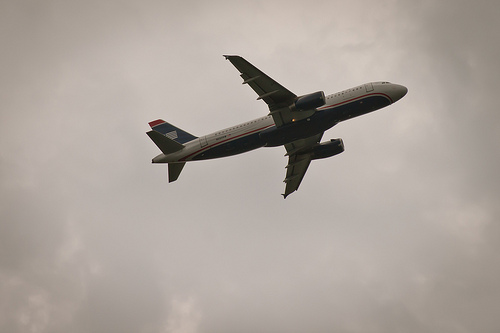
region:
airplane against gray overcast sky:
[20, 13, 478, 316]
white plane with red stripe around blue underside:
[136, 43, 409, 198]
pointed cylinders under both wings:
[219, 48, 297, 205]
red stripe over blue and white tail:
[141, 112, 199, 153]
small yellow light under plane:
[266, 98, 322, 143]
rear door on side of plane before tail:
[182, 123, 213, 166]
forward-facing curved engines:
[303, 77, 347, 161]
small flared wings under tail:
[146, 111, 195, 184]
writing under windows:
[208, 125, 242, 147]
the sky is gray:
[4, 4, 497, 327]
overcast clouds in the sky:
[1, 4, 498, 331]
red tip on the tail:
[148, 119, 163, 126]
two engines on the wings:
[295, 90, 343, 157]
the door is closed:
[366, 80, 373, 92]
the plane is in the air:
[147, 53, 408, 195]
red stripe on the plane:
[183, 90, 393, 162]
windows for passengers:
[211, 116, 272, 136]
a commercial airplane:
[145, 54, 407, 196]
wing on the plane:
[223, 53, 292, 112]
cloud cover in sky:
[4, 3, 496, 327]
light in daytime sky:
[3, 4, 495, 331]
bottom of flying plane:
[144, 54, 406, 198]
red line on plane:
[187, 90, 395, 160]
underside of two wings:
[227, 54, 326, 196]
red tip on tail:
[147, 117, 202, 144]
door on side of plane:
[364, 82, 375, 93]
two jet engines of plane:
[296, 90, 344, 156]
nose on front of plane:
[379, 80, 409, 102]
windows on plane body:
[212, 84, 364, 136]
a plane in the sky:
[147, 51, 411, 199]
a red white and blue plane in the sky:
[141, 50, 410, 201]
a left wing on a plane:
[279, 141, 336, 207]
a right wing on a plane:
[219, 53, 311, 108]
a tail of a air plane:
[146, 115, 196, 187]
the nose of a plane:
[389, 79, 412, 103]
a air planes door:
[364, 81, 374, 93]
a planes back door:
[194, 133, 211, 153]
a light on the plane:
[289, 113, 301, 128]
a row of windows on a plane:
[212, 118, 278, 135]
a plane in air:
[97, 18, 468, 227]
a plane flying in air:
[93, 39, 387, 206]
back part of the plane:
[150, 120, 227, 199]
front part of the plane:
[369, 55, 452, 158]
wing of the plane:
[203, 30, 303, 107]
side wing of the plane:
[293, 72, 325, 117]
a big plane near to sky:
[70, 14, 477, 285]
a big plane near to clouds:
[83, 27, 400, 254]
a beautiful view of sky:
[33, 31, 495, 306]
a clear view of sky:
[41, 2, 473, 293]